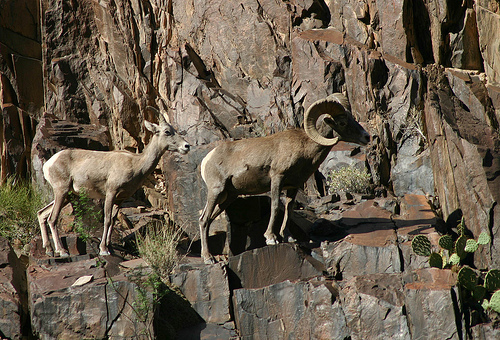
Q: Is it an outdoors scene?
A: Yes, it is outdoors.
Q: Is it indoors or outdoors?
A: It is outdoors.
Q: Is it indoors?
A: No, it is outdoors.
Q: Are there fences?
A: No, there are no fences.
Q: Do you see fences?
A: No, there are no fences.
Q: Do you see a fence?
A: No, there are no fences.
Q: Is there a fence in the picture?
A: No, there are no fences.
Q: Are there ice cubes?
A: No, there are no ice cubes.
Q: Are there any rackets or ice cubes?
A: No, there are no ice cubes or rackets.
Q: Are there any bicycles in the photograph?
A: No, there are no bicycles.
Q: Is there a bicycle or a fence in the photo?
A: No, there are no bicycles or fences.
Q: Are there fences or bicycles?
A: No, there are no bicycles or fences.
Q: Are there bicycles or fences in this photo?
A: No, there are no bicycles or fences.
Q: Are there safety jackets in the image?
A: No, there are no safety jackets.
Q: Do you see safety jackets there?
A: No, there are no safety jackets.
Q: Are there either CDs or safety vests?
A: No, there are no safety vests or cds.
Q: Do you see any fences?
A: No, there are no fences.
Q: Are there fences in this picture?
A: No, there are no fences.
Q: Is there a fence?
A: No, there are no fences.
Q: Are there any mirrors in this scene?
A: No, there are no mirrors.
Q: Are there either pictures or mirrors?
A: No, there are no mirrors or pictures.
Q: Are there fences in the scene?
A: No, there are no fences.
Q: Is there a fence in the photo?
A: No, there are no fences.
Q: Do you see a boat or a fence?
A: No, there are no fences or boats.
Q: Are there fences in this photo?
A: No, there are no fences.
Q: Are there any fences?
A: No, there are no fences.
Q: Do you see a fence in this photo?
A: No, there are no fences.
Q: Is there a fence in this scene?
A: No, there are no fences.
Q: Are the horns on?
A: Yes, the horns are on.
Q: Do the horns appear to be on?
A: Yes, the horns are on.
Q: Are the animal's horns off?
A: No, the horns are on.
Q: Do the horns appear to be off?
A: No, the horns are on.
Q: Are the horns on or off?
A: The horns are on.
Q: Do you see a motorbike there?
A: No, there are no motorcycles.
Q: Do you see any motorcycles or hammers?
A: No, there are no motorcycles or hammers.